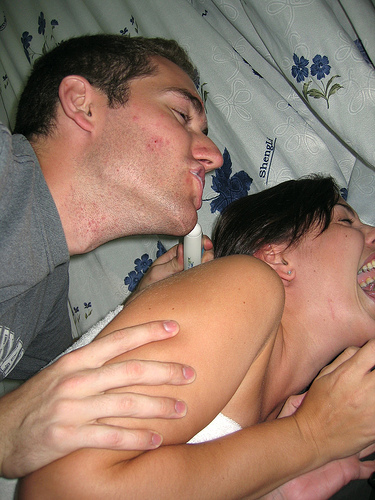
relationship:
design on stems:
[291, 52, 343, 108] [307, 79, 325, 94]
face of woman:
[298, 182, 373, 339] [6, 174, 374, 498]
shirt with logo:
[2, 124, 70, 383] [0, 325, 26, 378]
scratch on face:
[326, 297, 339, 324] [304, 184, 374, 337]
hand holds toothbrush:
[120, 237, 210, 304] [184, 221, 200, 272]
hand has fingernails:
[1, 308, 203, 487] [153, 317, 195, 456]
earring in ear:
[282, 267, 294, 277] [254, 238, 298, 283]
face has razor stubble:
[96, 60, 227, 241] [90, 124, 190, 235]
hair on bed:
[205, 169, 348, 265] [6, 1, 374, 491]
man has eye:
[5, 25, 232, 296] [169, 106, 193, 123]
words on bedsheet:
[255, 133, 280, 183] [228, 98, 300, 188]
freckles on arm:
[214, 276, 259, 314] [12, 246, 301, 496]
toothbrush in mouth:
[179, 217, 206, 268] [187, 160, 209, 207]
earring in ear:
[288, 271, 292, 275] [260, 241, 299, 283]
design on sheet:
[291, 52, 343, 108] [217, 13, 373, 161]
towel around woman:
[16, 303, 237, 498] [6, 174, 374, 498]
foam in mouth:
[192, 166, 209, 185] [189, 165, 210, 205]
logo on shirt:
[1, 327, 28, 378] [1, 120, 85, 391]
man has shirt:
[0, 33, 223, 479] [1, 120, 85, 391]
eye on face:
[162, 100, 197, 127] [117, 60, 228, 233]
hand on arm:
[1, 308, 203, 487] [12, 246, 301, 496]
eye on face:
[338, 212, 357, 226] [298, 191, 374, 333]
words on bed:
[255, 132, 280, 183] [0, 0, 375, 499]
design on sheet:
[272, 91, 310, 147] [213, 4, 363, 137]